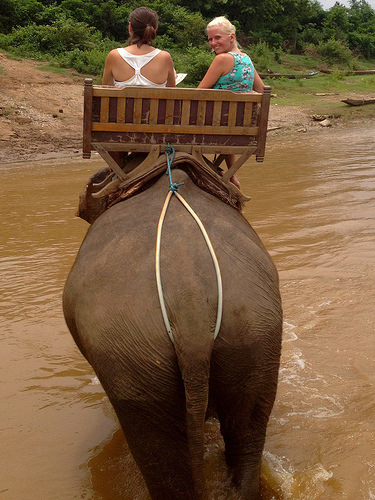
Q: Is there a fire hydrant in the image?
A: No, there are no fire hydrants.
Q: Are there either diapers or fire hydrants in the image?
A: No, there are no fire hydrants or diapers.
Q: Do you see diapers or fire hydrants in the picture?
A: No, there are no fire hydrants or diapers.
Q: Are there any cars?
A: No, there are no cars.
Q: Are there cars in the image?
A: No, there are no cars.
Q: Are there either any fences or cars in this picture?
A: No, there are no cars or fences.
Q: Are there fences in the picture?
A: No, there are no fences.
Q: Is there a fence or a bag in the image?
A: No, there are no fences or bags.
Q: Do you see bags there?
A: No, there are no bags.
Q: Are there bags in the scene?
A: No, there are no bags.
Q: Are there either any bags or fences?
A: No, there are no bags or fences.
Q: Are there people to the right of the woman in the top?
A: Yes, there is a person to the right of the woman.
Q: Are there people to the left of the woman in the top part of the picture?
A: No, the person is to the right of the woman.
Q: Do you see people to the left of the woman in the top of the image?
A: No, the person is to the right of the woman.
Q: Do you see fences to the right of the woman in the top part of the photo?
A: No, there is a person to the right of the woman.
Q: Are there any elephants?
A: Yes, there is an elephant.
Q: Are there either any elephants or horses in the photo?
A: Yes, there is an elephant.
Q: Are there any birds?
A: No, there are no birds.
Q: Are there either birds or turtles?
A: No, there are no birds or turtles.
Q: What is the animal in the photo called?
A: The animal is an elephant.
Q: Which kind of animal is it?
A: The animal is an elephant.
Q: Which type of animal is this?
A: This is an elephant.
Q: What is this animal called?
A: This is an elephant.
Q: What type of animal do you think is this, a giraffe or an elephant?
A: This is an elephant.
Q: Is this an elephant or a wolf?
A: This is an elephant.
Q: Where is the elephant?
A: The elephant is in the water.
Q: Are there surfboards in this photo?
A: No, there are no surfboards.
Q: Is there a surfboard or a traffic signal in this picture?
A: No, there are no surfboards or traffic lights.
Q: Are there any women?
A: Yes, there is a woman.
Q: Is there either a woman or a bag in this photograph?
A: Yes, there is a woman.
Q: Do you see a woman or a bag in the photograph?
A: Yes, there is a woman.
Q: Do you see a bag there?
A: No, there are no bags.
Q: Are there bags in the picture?
A: No, there are no bags.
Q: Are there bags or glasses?
A: No, there are no bags or glasses.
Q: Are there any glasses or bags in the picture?
A: No, there are no bags or glasses.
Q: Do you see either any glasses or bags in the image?
A: No, there are no bags or glasses.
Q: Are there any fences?
A: No, there are no fences.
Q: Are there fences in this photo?
A: No, there are no fences.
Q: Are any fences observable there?
A: No, there are no fences.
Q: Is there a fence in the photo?
A: No, there are no fences.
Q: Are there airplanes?
A: No, there are no airplanes.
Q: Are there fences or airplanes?
A: No, there are no airplanes or fences.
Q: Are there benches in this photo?
A: Yes, there is a bench.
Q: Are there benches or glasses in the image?
A: Yes, there is a bench.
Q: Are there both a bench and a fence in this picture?
A: No, there is a bench but no fences.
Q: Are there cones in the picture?
A: No, there are no cones.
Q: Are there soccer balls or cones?
A: No, there are no cones or soccer balls.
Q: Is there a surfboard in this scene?
A: No, there are no surfboards.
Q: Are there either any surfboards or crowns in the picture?
A: No, there are no surfboards or crowns.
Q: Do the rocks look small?
A: Yes, the rocks are small.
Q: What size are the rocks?
A: The rocks are small.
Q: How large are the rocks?
A: The rocks are small.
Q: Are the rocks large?
A: No, the rocks are small.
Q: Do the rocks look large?
A: No, the rocks are small.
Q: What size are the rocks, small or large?
A: The rocks are small.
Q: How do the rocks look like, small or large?
A: The rocks are small.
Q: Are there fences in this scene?
A: No, there are no fences.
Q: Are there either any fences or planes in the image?
A: No, there are no fences or planes.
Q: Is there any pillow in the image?
A: No, there are no pillows.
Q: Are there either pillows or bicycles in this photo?
A: No, there are no pillows or bicycles.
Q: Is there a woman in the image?
A: Yes, there is a woman.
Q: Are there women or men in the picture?
A: Yes, there is a woman.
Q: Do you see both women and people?
A: Yes, there are both a woman and a person.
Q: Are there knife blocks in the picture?
A: No, there are no knife blocks.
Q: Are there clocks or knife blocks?
A: No, there are no knife blocks or clocks.